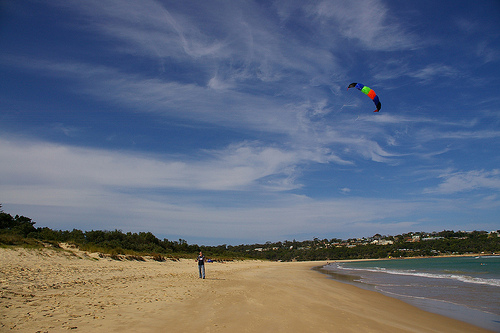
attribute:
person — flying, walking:
[198, 250, 208, 283]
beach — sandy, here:
[7, 254, 487, 326]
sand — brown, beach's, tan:
[9, 254, 464, 329]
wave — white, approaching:
[321, 255, 497, 300]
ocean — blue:
[323, 255, 499, 329]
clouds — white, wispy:
[19, 4, 493, 215]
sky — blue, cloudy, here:
[1, 2, 495, 235]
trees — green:
[0, 208, 500, 266]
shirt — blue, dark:
[198, 254, 206, 265]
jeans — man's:
[196, 266, 207, 279]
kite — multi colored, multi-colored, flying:
[345, 77, 389, 106]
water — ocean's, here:
[331, 237, 500, 318]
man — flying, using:
[198, 247, 207, 279]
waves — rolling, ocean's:
[330, 258, 496, 301]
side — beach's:
[7, 2, 394, 321]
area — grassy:
[9, 251, 255, 260]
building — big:
[364, 232, 397, 249]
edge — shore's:
[314, 251, 499, 329]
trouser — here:
[198, 261, 208, 274]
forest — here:
[7, 224, 493, 254]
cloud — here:
[14, 128, 299, 190]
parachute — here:
[348, 72, 390, 114]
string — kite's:
[208, 89, 353, 264]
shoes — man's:
[199, 273, 206, 279]